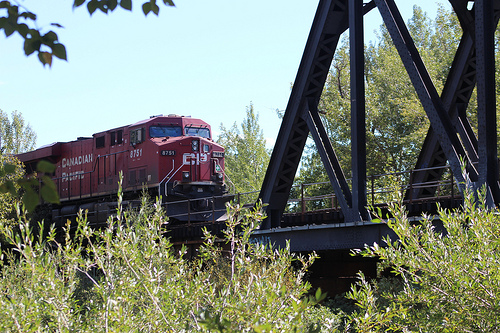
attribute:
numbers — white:
[127, 144, 144, 160]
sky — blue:
[1, 0, 475, 172]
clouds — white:
[183, 81, 324, 176]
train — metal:
[20, 123, 223, 220]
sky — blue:
[13, 6, 403, 165]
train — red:
[45, 97, 265, 255]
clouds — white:
[200, 57, 274, 142]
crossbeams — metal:
[231, 7, 498, 219]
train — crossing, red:
[0, 109, 226, 247]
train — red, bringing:
[1, 113, 227, 225]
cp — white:
[179, 146, 211, 168]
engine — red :
[17, 116, 235, 220]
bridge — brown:
[271, 45, 481, 270]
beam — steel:
[256, 0, 347, 228]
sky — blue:
[0, 1, 320, 143]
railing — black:
[1, 183, 498, 240]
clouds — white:
[77, 51, 137, 89]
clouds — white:
[78, 59, 150, 90]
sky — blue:
[1, 0, 498, 113]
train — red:
[1, 114, 234, 242]